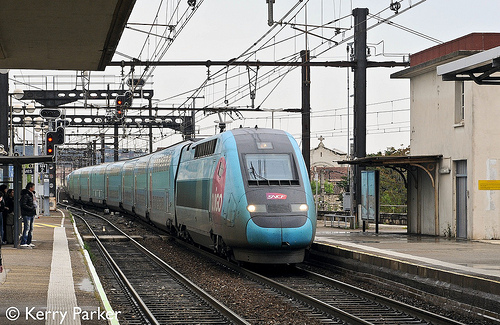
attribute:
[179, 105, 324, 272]
train car — blue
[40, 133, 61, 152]
light — red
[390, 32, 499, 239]
building — multiple story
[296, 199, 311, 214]
light — on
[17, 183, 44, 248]
man — standing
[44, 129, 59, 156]
light — traffic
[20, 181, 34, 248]
man — standing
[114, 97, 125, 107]
light — red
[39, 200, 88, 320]
line — white